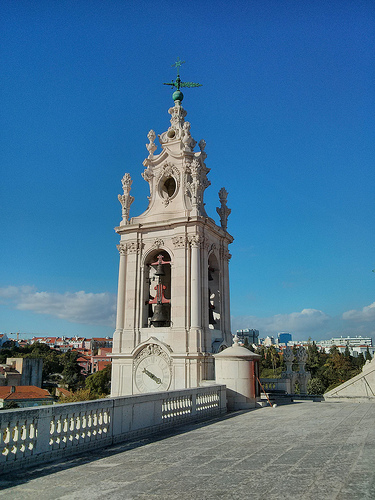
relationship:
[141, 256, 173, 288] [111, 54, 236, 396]
bell in clock tower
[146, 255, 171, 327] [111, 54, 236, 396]
bell in clock tower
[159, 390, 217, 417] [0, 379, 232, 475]
holes in wall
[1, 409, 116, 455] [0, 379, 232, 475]
holes in wall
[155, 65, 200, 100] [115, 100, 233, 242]
weather vane on roof